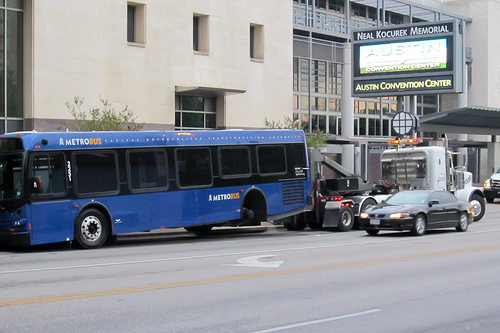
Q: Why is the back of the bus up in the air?
A: It's about to be towed.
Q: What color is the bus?
A: Blue.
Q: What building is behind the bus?
A: Austin Convention Center.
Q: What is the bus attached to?
A: Tow truck.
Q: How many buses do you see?
A: 1.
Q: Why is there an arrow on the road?
A: To show direction.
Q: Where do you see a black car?
A: On the road.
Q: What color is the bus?
A: Blue.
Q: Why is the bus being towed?
A: Flat tire on the rear.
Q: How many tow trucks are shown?
A: 1.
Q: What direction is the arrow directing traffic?
A: To the left.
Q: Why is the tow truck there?
A: To pull the bus.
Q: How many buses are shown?
A: 1.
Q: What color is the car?
A: Black.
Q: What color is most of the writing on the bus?
A: White.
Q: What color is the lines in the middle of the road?
A: Yellow.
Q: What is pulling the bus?
A: Towing.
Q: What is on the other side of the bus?
A: Building.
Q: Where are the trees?
A: Beside the bus.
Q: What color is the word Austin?
A: White.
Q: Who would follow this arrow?
A: Drivers.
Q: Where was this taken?
A: Austin.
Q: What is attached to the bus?
A: Tow truck.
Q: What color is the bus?
A: Blue.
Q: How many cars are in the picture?
A: One.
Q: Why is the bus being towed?
A: Broke down.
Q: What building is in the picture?
A: Austin Convention Center.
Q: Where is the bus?
A: Hooked up to the tow truck.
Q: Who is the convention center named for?
A: Neal Kocurek.